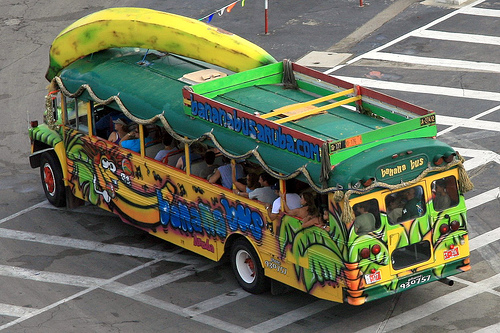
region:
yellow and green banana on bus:
[56, 8, 266, 74]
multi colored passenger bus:
[58, 69, 463, 310]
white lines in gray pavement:
[60, 258, 155, 313]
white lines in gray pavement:
[395, 17, 457, 52]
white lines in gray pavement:
[410, 30, 470, 76]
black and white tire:
[223, 243, 267, 285]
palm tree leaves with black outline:
[277, 206, 391, 289]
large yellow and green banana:
[45, 4, 277, 74]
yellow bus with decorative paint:
[25, 5, 475, 305]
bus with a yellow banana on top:
[27, 5, 472, 306]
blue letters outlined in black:
[155, 185, 266, 241]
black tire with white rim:
[225, 235, 268, 297]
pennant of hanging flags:
[195, 0, 247, 25]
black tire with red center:
[36, 149, 67, 210]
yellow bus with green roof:
[24, 5, 471, 304]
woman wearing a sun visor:
[103, 116, 129, 146]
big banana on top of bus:
[42, 6, 289, 98]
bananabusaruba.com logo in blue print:
[177, 90, 334, 166]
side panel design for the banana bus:
[29, 126, 354, 301]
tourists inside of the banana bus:
[72, 98, 344, 227]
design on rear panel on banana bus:
[341, 133, 473, 308]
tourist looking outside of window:
[101, 115, 137, 145]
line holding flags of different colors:
[191, 2, 285, 27]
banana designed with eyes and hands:
[84, 146, 181, 233]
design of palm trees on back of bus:
[271, 205, 476, 306]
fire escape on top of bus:
[176, 64, 243, 97]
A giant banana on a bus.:
[31, 13, 298, 83]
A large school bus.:
[16, 12, 484, 310]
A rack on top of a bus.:
[189, 45, 446, 157]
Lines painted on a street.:
[328, 1, 499, 101]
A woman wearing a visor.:
[102, 112, 127, 144]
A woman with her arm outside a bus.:
[273, 184, 315, 216]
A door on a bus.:
[377, 173, 449, 278]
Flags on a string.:
[176, 0, 300, 42]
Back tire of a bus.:
[223, 228, 275, 310]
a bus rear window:
[353, 197, 378, 235]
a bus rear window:
[385, 184, 426, 222]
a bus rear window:
[430, 175, 461, 210]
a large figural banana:
[45, 7, 274, 85]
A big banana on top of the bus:
[35, 29, 270, 98]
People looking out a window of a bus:
[282, 180, 332, 247]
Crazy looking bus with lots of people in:
[26, 62, 444, 261]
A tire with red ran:
[23, 118, 83, 224]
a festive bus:
[30, 3, 487, 323]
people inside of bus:
[66, 100, 321, 219]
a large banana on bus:
[43, 5, 280, 110]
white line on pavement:
[358, 42, 499, 91]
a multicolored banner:
[187, 0, 276, 42]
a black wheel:
[217, 225, 272, 292]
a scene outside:
[9, 0, 496, 332]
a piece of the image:
[88, 259, 97, 263]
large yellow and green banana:
[45, 5, 278, 82]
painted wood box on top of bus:
[180, 57, 436, 166]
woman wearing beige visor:
[105, 113, 127, 146]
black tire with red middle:
[35, 149, 67, 209]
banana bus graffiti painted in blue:
[153, 186, 265, 243]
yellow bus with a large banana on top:
[27, 6, 469, 307]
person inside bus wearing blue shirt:
[118, 124, 151, 151]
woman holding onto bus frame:
[278, 171, 318, 218]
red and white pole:
[262, 0, 269, 35]